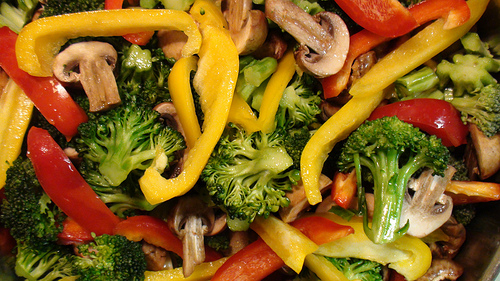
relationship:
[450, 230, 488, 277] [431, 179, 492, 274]
pan in corner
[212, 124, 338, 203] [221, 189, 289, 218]
broccoli has florets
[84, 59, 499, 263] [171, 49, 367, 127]
vegetables for stir fry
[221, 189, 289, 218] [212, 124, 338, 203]
florets on broccoli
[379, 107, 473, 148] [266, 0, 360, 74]
pepper near mushroom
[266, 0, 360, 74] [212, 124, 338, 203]
mushroom near broccoli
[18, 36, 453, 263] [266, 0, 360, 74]
salad has mushroom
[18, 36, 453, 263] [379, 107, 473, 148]
salad has pepper